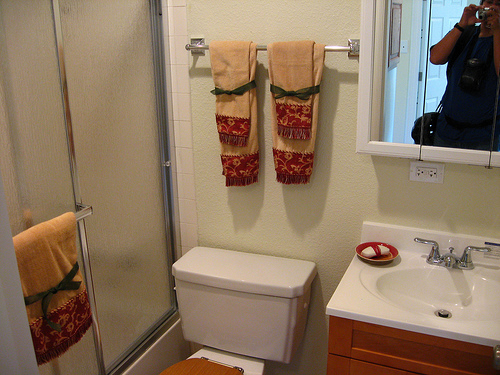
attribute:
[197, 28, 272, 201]
towel — brown, hanging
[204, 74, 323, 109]
ties — green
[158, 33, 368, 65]
holder — metal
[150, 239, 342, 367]
sink — white, walk, shiny, metal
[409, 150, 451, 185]
outlet — white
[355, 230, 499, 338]
sink — white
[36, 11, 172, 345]
door — glass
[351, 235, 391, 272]
dish — brown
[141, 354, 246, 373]
toilet — brown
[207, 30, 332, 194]
towels — hanging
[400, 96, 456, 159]
bag — black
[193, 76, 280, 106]
ribbon — green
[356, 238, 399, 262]
soap — white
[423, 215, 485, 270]
faucet — chrome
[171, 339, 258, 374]
seat — wooden